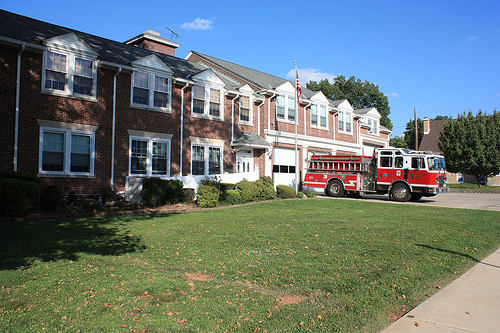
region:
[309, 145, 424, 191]
this is a lorry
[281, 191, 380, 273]
this is a grass area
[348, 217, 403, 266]
the grass is green in color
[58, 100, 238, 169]
this is a building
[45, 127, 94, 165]
this is the window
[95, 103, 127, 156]
this is the wall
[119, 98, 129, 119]
the wall is brown in color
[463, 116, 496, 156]
this is a tree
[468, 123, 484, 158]
the leaves are green in color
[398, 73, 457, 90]
this is the sky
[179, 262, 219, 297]
patch of brown grass on the ground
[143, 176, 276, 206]
large green bushes in front of building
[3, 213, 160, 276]
shadow of tree on the ground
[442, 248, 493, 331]
sidewalk has a spot on it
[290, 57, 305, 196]
flag pole in front of fire house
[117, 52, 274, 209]
fire house has two floors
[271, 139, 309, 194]
fire house garage door has three windows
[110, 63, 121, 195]
white storm drain on front of building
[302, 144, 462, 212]
red fire truck is parked in front of building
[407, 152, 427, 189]
words are printed on fire truck door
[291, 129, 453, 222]
Red and white fire truck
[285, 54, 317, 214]
Grey flag pole in front of building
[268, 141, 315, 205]
White garage door with windows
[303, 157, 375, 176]
Silver ladder on side of fire truck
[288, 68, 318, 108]
Blue, white, and red flag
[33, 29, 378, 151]
Building with a grey roof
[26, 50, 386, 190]
The building is made of brick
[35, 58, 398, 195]
The brick is red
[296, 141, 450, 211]
The fire truck is parked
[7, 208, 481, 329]
Brown leaves on the grass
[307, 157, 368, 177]
Ladder of a fire truck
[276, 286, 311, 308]
Dead spot in the grass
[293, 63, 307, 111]
American flag at fire department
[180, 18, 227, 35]
White cloud in a blue sky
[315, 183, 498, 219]
Fire Department driveway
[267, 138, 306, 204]
Garage door for fire truck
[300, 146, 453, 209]
Firetruck sitting in the driveway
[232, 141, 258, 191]
Entry doors to the fire department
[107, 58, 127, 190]
Downpipe for the gutter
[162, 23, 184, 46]
Antenna mounted to the roof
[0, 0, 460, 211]
a fire truck in front of fire station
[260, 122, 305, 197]
a large door of fire station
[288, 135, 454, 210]
fire truck is red and white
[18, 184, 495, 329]
a field of green grass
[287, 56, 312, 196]
the American flag in front of building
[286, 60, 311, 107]
American flag is white, red and blue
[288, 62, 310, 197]
a gray pole holding an American flag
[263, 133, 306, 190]
door of building is white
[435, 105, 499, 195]
a green tree in front a building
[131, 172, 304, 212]
green bushes in front a building